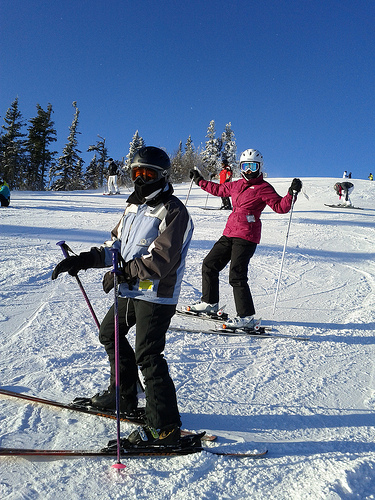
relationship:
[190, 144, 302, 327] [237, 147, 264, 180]
woman wearing helmet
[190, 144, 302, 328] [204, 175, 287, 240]
woman wearing coat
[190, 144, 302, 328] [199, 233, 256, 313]
woman wearing pants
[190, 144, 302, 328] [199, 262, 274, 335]
woman wearing boots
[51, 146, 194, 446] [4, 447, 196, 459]
man wearing writing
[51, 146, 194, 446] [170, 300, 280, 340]
man wearing black skis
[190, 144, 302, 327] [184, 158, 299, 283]
woman holding poles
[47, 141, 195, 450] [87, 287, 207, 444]
man wearing pants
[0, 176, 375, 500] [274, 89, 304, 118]
snow covering ground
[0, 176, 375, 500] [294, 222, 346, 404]
snow covering ground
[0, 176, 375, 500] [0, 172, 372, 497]
snow covering ground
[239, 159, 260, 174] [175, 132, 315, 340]
goggles on face of person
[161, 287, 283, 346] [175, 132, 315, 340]
skis on feet of person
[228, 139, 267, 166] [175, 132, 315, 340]
helmet on head of person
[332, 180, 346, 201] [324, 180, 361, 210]
scarf around neck of person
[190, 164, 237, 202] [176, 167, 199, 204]
arm holding ski pole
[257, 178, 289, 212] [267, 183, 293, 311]
arm holding ski pole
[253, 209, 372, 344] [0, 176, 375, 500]
ski tracks on snow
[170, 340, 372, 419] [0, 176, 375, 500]
ski tracks on snow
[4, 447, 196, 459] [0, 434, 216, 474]
writing on side of ski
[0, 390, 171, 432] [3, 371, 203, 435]
writing on side of ski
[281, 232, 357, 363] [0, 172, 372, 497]
snow covering ground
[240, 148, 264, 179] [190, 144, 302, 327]
helmet on head of woman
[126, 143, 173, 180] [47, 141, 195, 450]
helmet on head of man